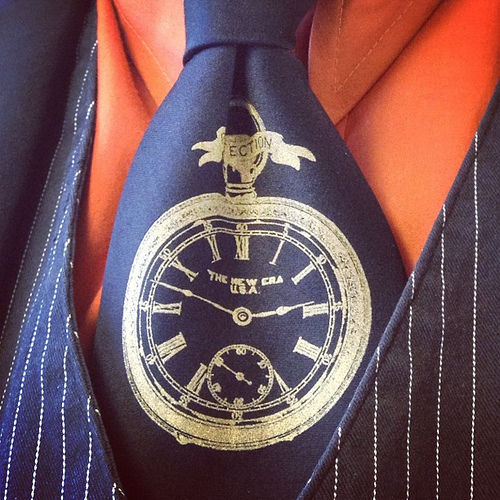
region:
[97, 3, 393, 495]
a blue tie on a shirt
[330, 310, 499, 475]
a piece of striped cloth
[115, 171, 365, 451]
a white symbol on a tie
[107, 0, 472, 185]
a orange shirt with a tie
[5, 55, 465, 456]
a strip shirt with a tie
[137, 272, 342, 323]
white hands on clock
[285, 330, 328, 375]
numbers on a clock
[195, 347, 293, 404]
a small white clock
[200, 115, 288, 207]
a writing on the top of tie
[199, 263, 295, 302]
a writing on the clock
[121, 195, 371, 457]
gold medallion design on navy tie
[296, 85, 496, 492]
left side of pin striped vest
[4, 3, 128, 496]
right side of pin striped vest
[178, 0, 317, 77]
knot on navy tie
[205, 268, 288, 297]
The New Era USA words in gold on tie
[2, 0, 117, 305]
blue suit jacket over vest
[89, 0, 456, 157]
collar of orange dress shirt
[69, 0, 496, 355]
orange dress shirt with tie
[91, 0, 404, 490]
blue silk tie with gold design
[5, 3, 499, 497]
photograph of pin striped vest and tie and jacket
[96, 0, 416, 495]
blue tie with gold design on neck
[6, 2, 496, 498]
blue and white pinstriped vest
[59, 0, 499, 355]
orange dress collared shirt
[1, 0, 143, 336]
blue blazer worn over vest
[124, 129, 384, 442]
gold circular clock on tie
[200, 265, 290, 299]
the new era usa written on tie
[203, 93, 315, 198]
gold flag design on watch on tie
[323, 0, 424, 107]
orange thread and stitching on orange shirt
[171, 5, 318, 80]
traditional knot on tie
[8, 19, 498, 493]
photograph of suited individual with tie and vest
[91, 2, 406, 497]
blue necktie with striped suit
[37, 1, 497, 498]
orange shirt and blue tie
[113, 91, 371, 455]
insignia on a necktie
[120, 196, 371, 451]
a pocket watch like insignia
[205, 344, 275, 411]
second hand illustration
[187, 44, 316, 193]
the dimple in the tie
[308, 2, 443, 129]
collar of the shirt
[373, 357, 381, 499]
pin stripe on the vest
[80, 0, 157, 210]
shirt not laying flat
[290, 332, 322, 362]
Roman numeral three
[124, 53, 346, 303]
Blue and gold tie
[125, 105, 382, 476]
Blue and gold tie